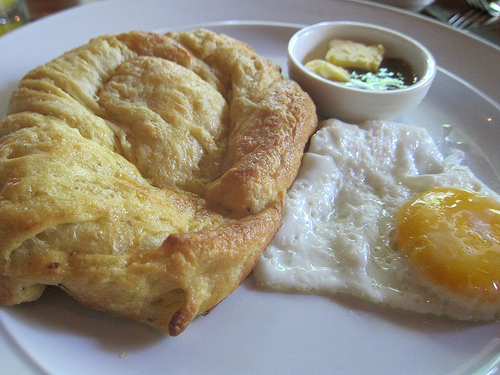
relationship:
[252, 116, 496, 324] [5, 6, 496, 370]
egg on top of plate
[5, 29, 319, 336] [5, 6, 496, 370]
danish on top of plate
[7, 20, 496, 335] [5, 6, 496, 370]
food on top of plate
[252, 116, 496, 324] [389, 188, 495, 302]
egg has yolk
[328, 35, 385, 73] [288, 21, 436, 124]
butter inside cup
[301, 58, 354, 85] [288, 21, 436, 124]
butter inside cup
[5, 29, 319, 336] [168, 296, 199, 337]
danish has part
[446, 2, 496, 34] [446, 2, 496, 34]
fork has fork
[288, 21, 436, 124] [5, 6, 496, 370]
cup on top of plate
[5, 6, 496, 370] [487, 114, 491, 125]
plate has reflection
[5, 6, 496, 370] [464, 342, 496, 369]
plate has reflection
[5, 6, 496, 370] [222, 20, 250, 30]
plate has reflection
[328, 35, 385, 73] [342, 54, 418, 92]
butter on top of syrup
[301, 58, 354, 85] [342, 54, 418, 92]
butter on top of syrup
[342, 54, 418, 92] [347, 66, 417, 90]
syrup has reflection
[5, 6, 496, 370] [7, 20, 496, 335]
plate holding food